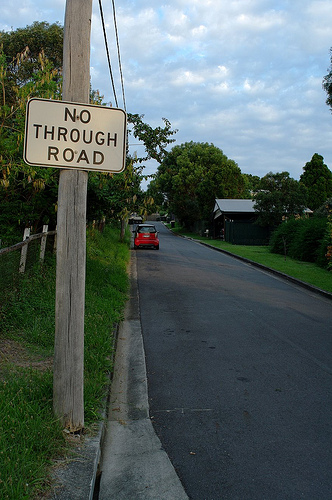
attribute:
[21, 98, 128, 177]
sign — black, white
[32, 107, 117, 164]
wording — black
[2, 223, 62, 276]
fence — wood, wooden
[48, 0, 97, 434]
pole — gray, wooden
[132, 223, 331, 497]
street — straight, dark, paved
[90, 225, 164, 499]
curb — cement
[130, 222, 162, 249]
car — small, red, parked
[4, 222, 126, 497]
grass — green, tall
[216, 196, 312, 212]
roof — gray, bright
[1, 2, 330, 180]
sky — cloudy, blue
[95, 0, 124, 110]
wire — power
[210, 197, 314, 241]
building — green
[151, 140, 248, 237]
tree — green, filled, tall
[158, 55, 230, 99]
cloud — white